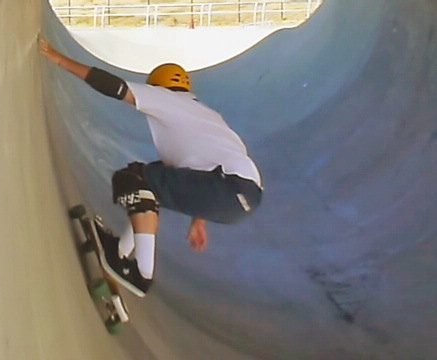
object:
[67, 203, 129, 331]
skateboard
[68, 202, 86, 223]
wheel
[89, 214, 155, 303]
shoes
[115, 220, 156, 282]
socks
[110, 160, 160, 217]
knee pads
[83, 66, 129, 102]
elbow pads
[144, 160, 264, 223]
shorts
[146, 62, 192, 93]
helmet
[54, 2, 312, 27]
rails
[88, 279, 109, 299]
wheel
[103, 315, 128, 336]
wheel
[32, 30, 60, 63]
hand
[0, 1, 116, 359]
wall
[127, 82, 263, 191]
shirt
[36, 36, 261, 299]
man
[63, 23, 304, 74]
ground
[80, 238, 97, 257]
wheel